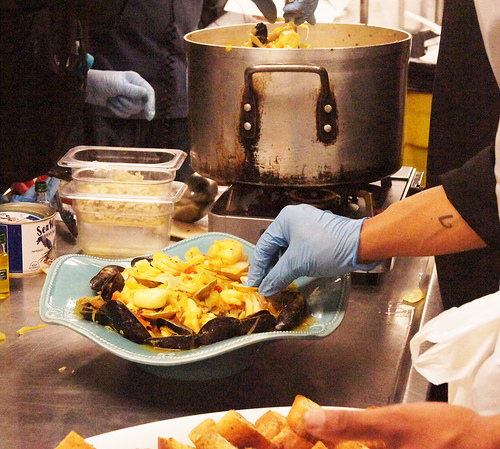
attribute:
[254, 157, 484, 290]
worker — arranging 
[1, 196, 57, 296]
ingredients — multiple 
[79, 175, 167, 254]
dish — containing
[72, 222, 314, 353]
dish — blue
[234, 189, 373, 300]
gloves — blue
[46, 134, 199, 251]
containers — clear, plastic, double stacked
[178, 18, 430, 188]
pot — big, metal, burnt, large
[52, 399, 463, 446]
plate — white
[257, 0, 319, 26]
hand — blue, gloved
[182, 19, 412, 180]
pot — silver, large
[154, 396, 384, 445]
bread — slices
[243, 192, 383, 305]
gloves — blue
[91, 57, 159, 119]
gloves — blue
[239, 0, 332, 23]
gloves — blue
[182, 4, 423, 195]
pot — silver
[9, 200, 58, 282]
can — open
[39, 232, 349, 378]
bowl — decorative, warped, blue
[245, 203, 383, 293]
glove — blue, latex, plastic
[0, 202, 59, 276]
can — blue, white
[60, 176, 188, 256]
container — clear, plastic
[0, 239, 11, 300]
bottle — small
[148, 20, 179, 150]
wire — black, curly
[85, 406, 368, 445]
plate — white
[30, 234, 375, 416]
bowl — blue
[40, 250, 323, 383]
platter — large, wavy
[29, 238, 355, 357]
bowl — wavy, blue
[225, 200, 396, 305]
glove — blue, latex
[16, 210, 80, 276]
can — blue, white, small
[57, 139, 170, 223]
containers — empty, plastic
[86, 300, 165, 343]
mussel — cooked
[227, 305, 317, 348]
mussel — cooked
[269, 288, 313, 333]
mussel — cooked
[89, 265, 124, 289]
mussel — cooked